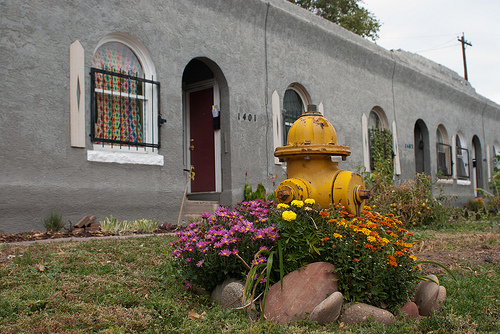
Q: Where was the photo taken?
A: It was taken at the yard.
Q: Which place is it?
A: It is a yard.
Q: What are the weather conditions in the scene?
A: It is cloudy.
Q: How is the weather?
A: It is cloudy.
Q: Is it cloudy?
A: Yes, it is cloudy.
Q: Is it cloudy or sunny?
A: It is cloudy.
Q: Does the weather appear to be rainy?
A: No, it is cloudy.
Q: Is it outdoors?
A: Yes, it is outdoors.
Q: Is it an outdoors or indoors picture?
A: It is outdoors.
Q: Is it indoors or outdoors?
A: It is outdoors.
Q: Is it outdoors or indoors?
A: It is outdoors.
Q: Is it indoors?
A: No, it is outdoors.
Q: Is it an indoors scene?
A: No, it is outdoors.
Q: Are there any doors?
A: Yes, there is a door.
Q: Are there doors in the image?
A: Yes, there is a door.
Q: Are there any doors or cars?
A: Yes, there is a door.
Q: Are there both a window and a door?
A: Yes, there are both a door and a window.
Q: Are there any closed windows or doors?
A: Yes, there is a closed door.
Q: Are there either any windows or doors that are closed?
A: Yes, the door is closed.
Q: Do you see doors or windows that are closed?
A: Yes, the door is closed.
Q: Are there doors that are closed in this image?
A: Yes, there is a closed door.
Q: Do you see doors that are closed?
A: Yes, there is a door that is closed.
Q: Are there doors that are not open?
A: Yes, there is an closed door.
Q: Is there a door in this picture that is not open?
A: Yes, there is an closed door.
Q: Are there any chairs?
A: No, there are no chairs.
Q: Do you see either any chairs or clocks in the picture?
A: No, there are no chairs or clocks.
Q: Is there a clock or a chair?
A: No, there are no chairs or clocks.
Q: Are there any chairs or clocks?
A: No, there are no chairs or clocks.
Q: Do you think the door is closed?
A: Yes, the door is closed.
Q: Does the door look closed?
A: Yes, the door is closed.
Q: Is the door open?
A: No, the door is closed.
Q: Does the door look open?
A: No, the door is closed.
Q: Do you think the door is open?
A: No, the door is closed.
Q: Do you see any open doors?
A: No, there is a door but it is closed.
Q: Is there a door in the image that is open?
A: No, there is a door but it is closed.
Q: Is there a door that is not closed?
A: No, there is a door but it is closed.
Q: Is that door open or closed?
A: The door is closed.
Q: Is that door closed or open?
A: The door is closed.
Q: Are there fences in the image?
A: No, there are no fences.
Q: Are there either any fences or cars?
A: No, there are no fences or cars.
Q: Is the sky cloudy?
A: Yes, the sky is cloudy.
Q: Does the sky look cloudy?
A: Yes, the sky is cloudy.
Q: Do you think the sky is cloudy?
A: Yes, the sky is cloudy.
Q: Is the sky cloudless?
A: No, the sky is cloudy.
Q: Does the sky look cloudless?
A: No, the sky is cloudy.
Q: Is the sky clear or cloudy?
A: The sky is cloudy.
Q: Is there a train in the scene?
A: No, there are no trains.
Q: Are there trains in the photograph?
A: No, there are no trains.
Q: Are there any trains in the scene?
A: No, there are no trains.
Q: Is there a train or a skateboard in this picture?
A: No, there are no trains or skateboards.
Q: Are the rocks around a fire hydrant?
A: Yes, the rocks are around a fire hydrant.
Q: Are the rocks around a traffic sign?
A: No, the rocks are around a fire hydrant.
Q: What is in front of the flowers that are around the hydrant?
A: The rocks are in front of the flowers.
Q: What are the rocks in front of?
A: The rocks are in front of the flowers.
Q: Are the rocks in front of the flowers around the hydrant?
A: Yes, the rocks are in front of the flowers.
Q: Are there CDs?
A: No, there are no cds.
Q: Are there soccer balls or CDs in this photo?
A: No, there are no CDs or soccer balls.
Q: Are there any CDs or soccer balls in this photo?
A: No, there are no CDs or soccer balls.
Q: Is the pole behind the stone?
A: Yes, the pole is behind the stone.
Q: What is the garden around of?
A: The garden is around the fire hydrant.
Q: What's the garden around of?
A: The garden is around the fire hydrant.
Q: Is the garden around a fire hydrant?
A: Yes, the garden is around a fire hydrant.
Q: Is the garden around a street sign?
A: No, the garden is around a fire hydrant.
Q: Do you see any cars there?
A: No, there are no cars.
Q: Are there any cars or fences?
A: No, there are no cars or fences.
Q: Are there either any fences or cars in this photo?
A: No, there are no cars or fences.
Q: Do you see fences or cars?
A: No, there are no cars or fences.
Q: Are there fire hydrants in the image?
A: Yes, there is a fire hydrant.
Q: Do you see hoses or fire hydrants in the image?
A: Yes, there is a fire hydrant.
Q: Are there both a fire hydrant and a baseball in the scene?
A: No, there is a fire hydrant but no baseballs.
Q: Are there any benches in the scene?
A: No, there are no benches.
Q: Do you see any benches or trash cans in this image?
A: No, there are no benches or trash cans.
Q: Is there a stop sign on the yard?
A: No, there is a fire hydrant on the yard.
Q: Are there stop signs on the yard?
A: No, there is a fire hydrant on the yard.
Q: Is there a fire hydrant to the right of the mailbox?
A: Yes, there is a fire hydrant to the right of the mailbox.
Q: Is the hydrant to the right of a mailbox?
A: Yes, the hydrant is to the right of a mailbox.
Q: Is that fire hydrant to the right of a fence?
A: No, the fire hydrant is to the right of a mailbox.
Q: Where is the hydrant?
A: The hydrant is in the yard.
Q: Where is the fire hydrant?
A: The hydrant is in the yard.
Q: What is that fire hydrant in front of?
A: The fire hydrant is in front of the stone.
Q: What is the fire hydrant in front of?
A: The fire hydrant is in front of the stone.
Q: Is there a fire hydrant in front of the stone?
A: Yes, there is a fire hydrant in front of the stone.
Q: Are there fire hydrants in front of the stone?
A: Yes, there is a fire hydrant in front of the stone.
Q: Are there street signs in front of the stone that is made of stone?
A: No, there is a fire hydrant in front of the stone.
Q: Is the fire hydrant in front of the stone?
A: Yes, the fire hydrant is in front of the stone.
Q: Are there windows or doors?
A: Yes, there is a window.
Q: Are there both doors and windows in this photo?
A: Yes, there are both a window and a door.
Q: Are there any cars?
A: No, there are no cars.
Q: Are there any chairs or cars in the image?
A: No, there are no cars or chairs.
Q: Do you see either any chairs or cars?
A: No, there are no cars or chairs.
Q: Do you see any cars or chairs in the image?
A: No, there are no cars or chairs.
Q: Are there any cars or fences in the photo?
A: No, there are no cars or fences.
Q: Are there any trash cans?
A: No, there are no trash cans.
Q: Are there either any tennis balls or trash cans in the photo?
A: No, there are no trash cans or tennis balls.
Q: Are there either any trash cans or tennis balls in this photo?
A: No, there are no trash cans or tennis balls.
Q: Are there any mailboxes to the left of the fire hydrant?
A: Yes, there is a mailbox to the left of the fire hydrant.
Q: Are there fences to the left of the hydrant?
A: No, there is a mailbox to the left of the hydrant.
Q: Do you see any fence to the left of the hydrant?
A: No, there is a mailbox to the left of the hydrant.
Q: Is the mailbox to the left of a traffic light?
A: No, the mailbox is to the left of the fire hydrant.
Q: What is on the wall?
A: The mailbox is on the wall.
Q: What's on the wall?
A: The mailbox is on the wall.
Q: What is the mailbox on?
A: The mailbox is on the wall.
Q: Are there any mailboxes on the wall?
A: Yes, there is a mailbox on the wall.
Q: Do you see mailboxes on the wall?
A: Yes, there is a mailbox on the wall.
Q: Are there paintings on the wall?
A: No, there is a mailbox on the wall.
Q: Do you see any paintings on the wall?
A: No, there is a mailbox on the wall.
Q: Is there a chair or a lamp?
A: No, there are no chairs or lamps.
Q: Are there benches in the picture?
A: No, there are no benches.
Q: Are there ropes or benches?
A: No, there are no benches or ropes.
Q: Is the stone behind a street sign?
A: No, the stone is behind a fire hydrant.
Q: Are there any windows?
A: Yes, there are windows.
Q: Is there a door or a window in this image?
A: Yes, there are windows.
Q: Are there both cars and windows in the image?
A: No, there are windows but no cars.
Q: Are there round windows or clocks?
A: Yes, there are round windows.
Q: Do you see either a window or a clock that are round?
A: Yes, the windows are round.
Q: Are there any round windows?
A: Yes, there are round windows.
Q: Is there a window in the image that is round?
A: Yes, there are windows that are round.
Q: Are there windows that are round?
A: Yes, there are windows that are round.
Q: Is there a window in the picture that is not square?
A: Yes, there are round windows.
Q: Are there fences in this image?
A: No, there are no fences.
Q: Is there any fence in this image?
A: No, there are no fences.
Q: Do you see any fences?
A: No, there are no fences.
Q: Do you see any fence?
A: No, there are no fences.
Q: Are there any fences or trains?
A: No, there are no fences or trains.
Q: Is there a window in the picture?
A: Yes, there is a window.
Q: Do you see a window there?
A: Yes, there is a window.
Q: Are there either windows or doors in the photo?
A: Yes, there is a window.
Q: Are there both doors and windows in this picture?
A: Yes, there are both a window and a door.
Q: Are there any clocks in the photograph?
A: No, there are no clocks.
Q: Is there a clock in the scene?
A: No, there are no clocks.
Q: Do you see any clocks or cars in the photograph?
A: No, there are no clocks or cars.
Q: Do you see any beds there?
A: No, there are no beds.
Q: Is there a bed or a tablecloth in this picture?
A: No, there are no beds or tablecloths.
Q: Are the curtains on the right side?
A: No, the curtains are on the left of the image.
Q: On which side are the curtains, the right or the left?
A: The curtains are on the left of the image.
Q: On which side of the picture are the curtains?
A: The curtains are on the left of the image.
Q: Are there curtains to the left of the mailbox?
A: Yes, there are curtains to the left of the mailbox.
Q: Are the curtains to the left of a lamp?
A: No, the curtains are to the left of the mailbox.